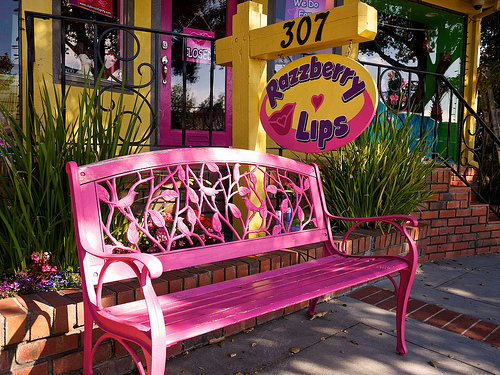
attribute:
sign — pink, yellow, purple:
[256, 53, 376, 150]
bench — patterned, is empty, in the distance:
[60, 144, 420, 374]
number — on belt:
[280, 10, 330, 47]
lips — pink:
[263, 102, 295, 134]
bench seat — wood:
[85, 237, 430, 349]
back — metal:
[75, 147, 330, 287]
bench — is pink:
[40, 140, 440, 337]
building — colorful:
[4, 3, 237, 145]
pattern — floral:
[94, 160, 323, 264]